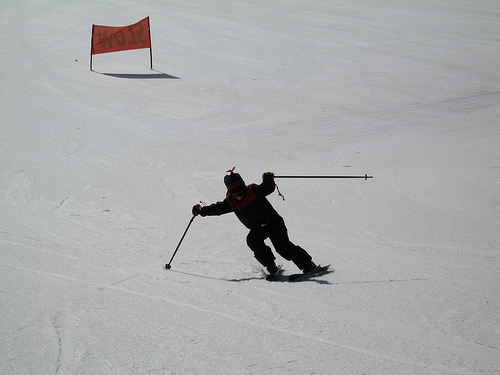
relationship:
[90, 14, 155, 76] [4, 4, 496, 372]
orange slow sign in snow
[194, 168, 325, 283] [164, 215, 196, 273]
skier with ski pole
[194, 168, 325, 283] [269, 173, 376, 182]
skier has ski pole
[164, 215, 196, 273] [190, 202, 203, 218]
ski pole in hand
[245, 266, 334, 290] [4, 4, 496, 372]
skis in snow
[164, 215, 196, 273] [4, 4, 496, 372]
ski pole in snow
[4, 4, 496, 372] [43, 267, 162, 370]
snow with tracks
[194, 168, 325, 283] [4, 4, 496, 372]
skier in snow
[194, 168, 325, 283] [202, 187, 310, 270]
skier dressed black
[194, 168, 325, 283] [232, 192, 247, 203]
skier wearing mask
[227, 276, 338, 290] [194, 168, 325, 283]
shadow of skier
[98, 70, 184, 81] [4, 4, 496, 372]
sign shadow in snow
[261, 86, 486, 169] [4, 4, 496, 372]
ski tracks in snow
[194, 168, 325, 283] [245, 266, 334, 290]
skier on skis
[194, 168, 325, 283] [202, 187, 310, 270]
skier wearing black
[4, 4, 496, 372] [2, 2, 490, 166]
snow on slope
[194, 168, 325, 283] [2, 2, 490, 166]
skier on slope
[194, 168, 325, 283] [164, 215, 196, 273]
skier has ski pole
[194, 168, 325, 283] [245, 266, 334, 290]
skier using skis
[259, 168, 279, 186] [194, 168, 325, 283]
glove on skier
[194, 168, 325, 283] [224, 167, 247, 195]
skier has hat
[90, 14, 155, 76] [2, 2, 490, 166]
orange slow sign down slope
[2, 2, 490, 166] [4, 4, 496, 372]
slope in snow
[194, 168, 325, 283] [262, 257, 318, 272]
skier wearing boots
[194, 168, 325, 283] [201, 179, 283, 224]
skier wearing sweater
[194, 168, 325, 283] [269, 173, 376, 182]
skier holding ski pole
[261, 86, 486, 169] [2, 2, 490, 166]
ski tracks are down slope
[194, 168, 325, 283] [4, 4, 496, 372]
skier skiing in snow